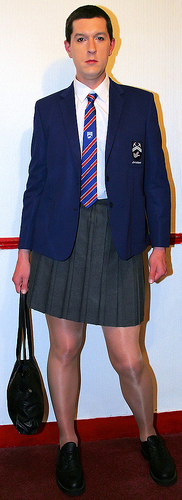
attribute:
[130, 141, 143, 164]
emblem — black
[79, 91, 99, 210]
neck tie — blue, red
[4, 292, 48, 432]
purse — black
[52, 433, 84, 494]
shoe — black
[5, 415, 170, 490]
floor — room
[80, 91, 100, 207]
tie — red, blue, striped, blue striped, red, white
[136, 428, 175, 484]
shoe — black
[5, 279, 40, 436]
purse — black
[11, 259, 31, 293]
hand — person's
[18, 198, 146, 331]
skirt — dark gray, pleated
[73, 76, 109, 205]
shirt — white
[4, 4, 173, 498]
person — standing up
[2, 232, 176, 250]
strip — red, painted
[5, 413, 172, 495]
carpet — red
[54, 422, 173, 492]
feet — person's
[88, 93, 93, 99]
stripe — red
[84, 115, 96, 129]
stripe — red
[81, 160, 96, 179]
stripe — red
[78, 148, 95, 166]
stripe — red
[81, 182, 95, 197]
stripe — red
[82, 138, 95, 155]
stripe — red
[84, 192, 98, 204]
stripe — red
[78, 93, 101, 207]
tie — blue, white, striped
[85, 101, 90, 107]
stripe — red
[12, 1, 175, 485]
man — woman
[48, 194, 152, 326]
skirt — grey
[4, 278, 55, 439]
purse — large, black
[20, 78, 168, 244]
blazer — blue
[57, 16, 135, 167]
man — posing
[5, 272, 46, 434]
purse — black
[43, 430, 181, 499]
shoe — black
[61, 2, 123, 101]
man — standing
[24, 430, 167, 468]
carpet — maroon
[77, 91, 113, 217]
tie — red, blue, striped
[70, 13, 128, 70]
face — mans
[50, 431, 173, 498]
shoe — black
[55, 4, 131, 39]
hair — black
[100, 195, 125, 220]
button — black, bottom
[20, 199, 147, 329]
clothing — article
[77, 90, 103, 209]
clothing — article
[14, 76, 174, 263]
clothing — article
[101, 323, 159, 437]
clothing — article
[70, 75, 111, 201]
clothing — article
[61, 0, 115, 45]
hair — short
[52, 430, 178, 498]
shoes — black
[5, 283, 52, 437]
bag — black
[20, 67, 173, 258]
blazer — blue 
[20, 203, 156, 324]
skirt —  grey pleated 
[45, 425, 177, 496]
shoes — black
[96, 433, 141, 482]
carpet — red 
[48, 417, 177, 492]
shoes — black 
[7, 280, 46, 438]
purse — black 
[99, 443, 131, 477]
carpet — Red 